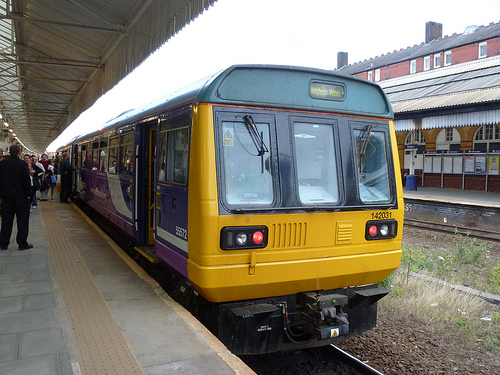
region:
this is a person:
[7, 145, 34, 247]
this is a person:
[21, 154, 33, 164]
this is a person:
[27, 151, 38, 168]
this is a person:
[59, 153, 75, 202]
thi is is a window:
[373, 67, 385, 92]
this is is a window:
[441, 47, 457, 74]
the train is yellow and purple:
[116, 92, 409, 280]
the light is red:
[251, 230, 263, 243]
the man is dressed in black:
[8, 156, 31, 258]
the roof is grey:
[455, 27, 480, 42]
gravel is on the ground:
[393, 332, 430, 373]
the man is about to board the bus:
[58, 151, 85, 202]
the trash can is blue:
[404, 171, 424, 193]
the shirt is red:
[40, 158, 47, 166]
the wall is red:
[457, 47, 472, 64]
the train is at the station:
[49, 112, 403, 364]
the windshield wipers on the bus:
[214, 91, 394, 220]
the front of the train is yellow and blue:
[199, 56, 401, 296]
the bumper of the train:
[207, 257, 405, 294]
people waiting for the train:
[5, 119, 65, 251]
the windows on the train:
[56, 128, 191, 192]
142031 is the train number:
[363, 192, 402, 234]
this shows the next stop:
[291, 67, 365, 114]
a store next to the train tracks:
[395, 63, 499, 211]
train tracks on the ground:
[408, 205, 499, 323]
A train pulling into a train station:
[44, 59, 411, 374]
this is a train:
[170, 66, 375, 288]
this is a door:
[137, 120, 159, 247]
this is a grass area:
[399, 278, 464, 334]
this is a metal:
[339, 347, 369, 373]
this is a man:
[7, 140, 40, 239]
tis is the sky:
[249, 10, 306, 51]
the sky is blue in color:
[252, 21, 284, 44]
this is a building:
[422, 41, 499, 227]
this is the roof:
[411, 70, 486, 107]